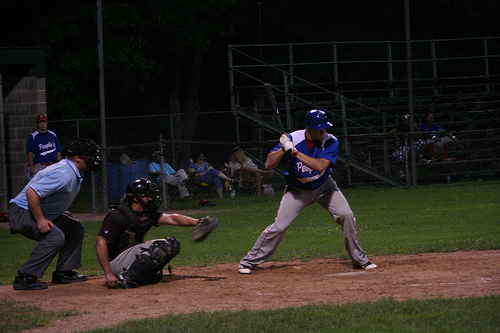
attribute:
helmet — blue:
[306, 108, 335, 133]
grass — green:
[0, 183, 496, 331]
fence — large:
[88, 127, 498, 209]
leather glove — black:
[187, 212, 222, 245]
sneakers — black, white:
[219, 260, 389, 275]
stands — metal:
[223, 40, 496, 189]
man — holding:
[234, 101, 382, 282]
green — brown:
[403, 193, 491, 247]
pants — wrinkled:
[239, 176, 372, 268]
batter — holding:
[235, 79, 376, 276]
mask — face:
[64, 129, 104, 169]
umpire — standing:
[9, 131, 108, 300]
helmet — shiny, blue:
[304, 106, 331, 133]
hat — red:
[33, 109, 50, 122]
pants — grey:
[244, 175, 367, 262]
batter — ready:
[257, 82, 376, 266]